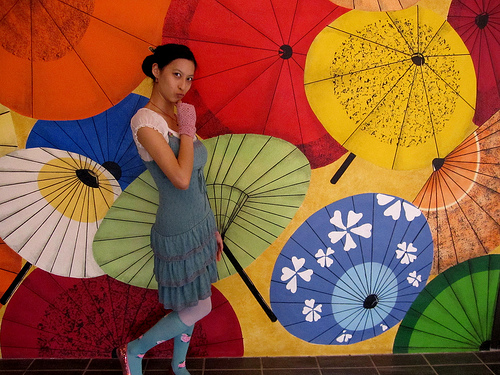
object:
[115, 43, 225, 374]
person